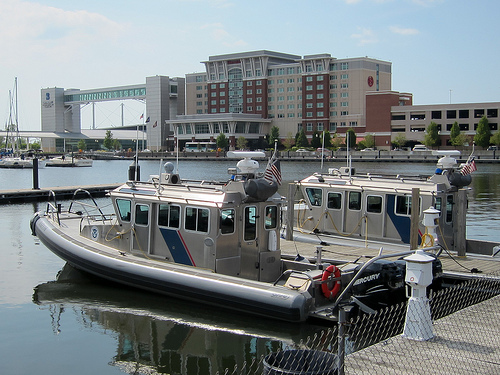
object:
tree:
[470, 114, 494, 149]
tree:
[213, 127, 229, 152]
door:
[131, 198, 153, 255]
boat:
[30, 125, 442, 324]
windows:
[116, 193, 132, 225]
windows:
[131, 201, 151, 230]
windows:
[156, 200, 183, 232]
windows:
[183, 204, 213, 234]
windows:
[217, 207, 236, 235]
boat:
[281, 131, 500, 265]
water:
[0, 159, 500, 373]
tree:
[265, 127, 282, 146]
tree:
[293, 126, 311, 150]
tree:
[307, 130, 323, 151]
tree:
[423, 120, 440, 149]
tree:
[447, 121, 466, 147]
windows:
[207, 79, 220, 93]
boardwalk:
[281, 221, 500, 283]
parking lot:
[284, 142, 463, 159]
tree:
[213, 131, 230, 151]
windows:
[303, 82, 317, 94]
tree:
[343, 126, 361, 151]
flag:
[258, 136, 284, 188]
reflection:
[32, 262, 339, 373]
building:
[169, 49, 412, 149]